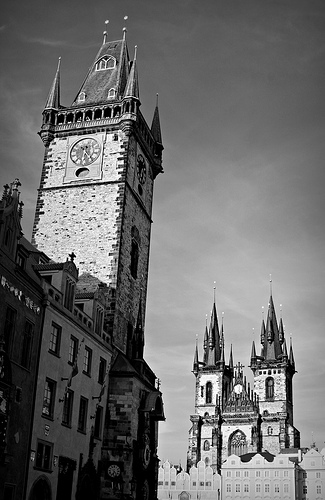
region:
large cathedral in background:
[183, 268, 300, 472]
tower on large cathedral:
[26, 7, 175, 354]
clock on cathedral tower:
[65, 133, 105, 173]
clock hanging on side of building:
[91, 456, 130, 480]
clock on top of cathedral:
[230, 381, 245, 396]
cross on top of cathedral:
[229, 359, 246, 376]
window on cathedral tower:
[122, 217, 148, 282]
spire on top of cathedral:
[266, 269, 274, 306]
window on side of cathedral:
[45, 319, 62, 359]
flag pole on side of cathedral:
[55, 332, 89, 417]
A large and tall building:
[186, 277, 297, 471]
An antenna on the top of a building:
[210, 280, 217, 303]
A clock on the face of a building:
[69, 136, 99, 165]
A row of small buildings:
[159, 453, 323, 496]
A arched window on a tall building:
[264, 376, 275, 398]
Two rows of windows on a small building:
[225, 469, 291, 493]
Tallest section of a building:
[73, 14, 130, 103]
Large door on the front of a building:
[227, 429, 247, 456]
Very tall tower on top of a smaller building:
[31, 14, 165, 352]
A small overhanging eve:
[143, 389, 165, 422]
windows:
[49, 326, 62, 357]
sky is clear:
[182, 240, 282, 282]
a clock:
[104, 463, 123, 477]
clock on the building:
[103, 458, 128, 478]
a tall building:
[183, 286, 304, 455]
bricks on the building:
[111, 398, 136, 432]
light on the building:
[52, 223, 116, 255]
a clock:
[68, 141, 101, 163]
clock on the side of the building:
[132, 151, 159, 191]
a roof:
[89, 77, 109, 93]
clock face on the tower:
[60, 128, 111, 178]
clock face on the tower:
[120, 139, 156, 199]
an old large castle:
[182, 269, 315, 496]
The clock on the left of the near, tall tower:
[67, 136, 104, 168]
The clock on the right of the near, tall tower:
[132, 151, 150, 188]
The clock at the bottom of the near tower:
[104, 460, 127, 485]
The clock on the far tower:
[231, 380, 247, 399]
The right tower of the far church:
[245, 265, 307, 453]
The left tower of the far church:
[183, 277, 235, 465]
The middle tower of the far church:
[219, 357, 262, 456]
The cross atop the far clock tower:
[229, 358, 247, 377]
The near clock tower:
[29, 11, 167, 361]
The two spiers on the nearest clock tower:
[97, 13, 133, 41]